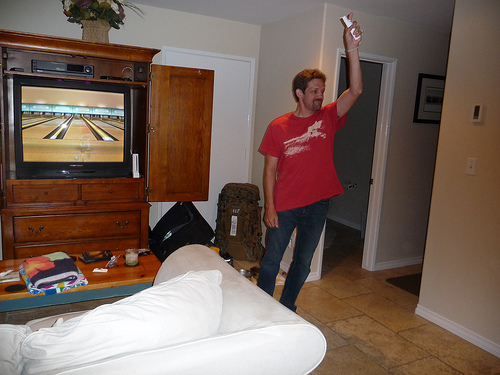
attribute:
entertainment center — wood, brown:
[2, 22, 241, 273]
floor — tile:
[0, 271, 497, 373]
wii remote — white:
[338, 13, 363, 44]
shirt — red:
[257, 99, 349, 212]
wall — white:
[426, 16, 497, 343]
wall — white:
[254, 15, 309, 117]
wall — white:
[125, 9, 252, 236]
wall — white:
[354, 18, 423, 281]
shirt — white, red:
[259, 107, 352, 211]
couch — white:
[0, 242, 336, 374]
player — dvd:
[25, 55, 99, 80]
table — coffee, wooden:
[0, 230, 194, 315]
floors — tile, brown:
[251, 214, 469, 371]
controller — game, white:
[339, 15, 360, 39]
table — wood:
[0, 241, 163, 318]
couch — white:
[21, 264, 252, 349]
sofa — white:
[1, 240, 329, 373]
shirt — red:
[250, 107, 363, 218]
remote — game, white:
[337, 14, 366, 46]